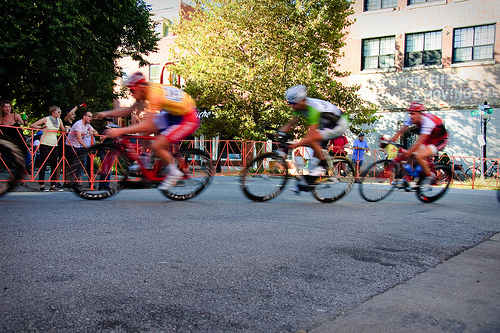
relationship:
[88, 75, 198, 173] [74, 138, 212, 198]
person riding bike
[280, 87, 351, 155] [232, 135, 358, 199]
person riding bike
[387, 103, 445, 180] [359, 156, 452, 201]
person riding bike